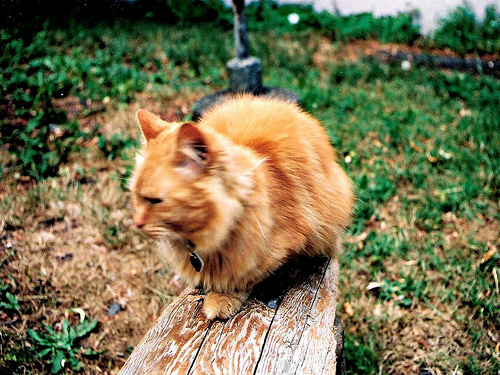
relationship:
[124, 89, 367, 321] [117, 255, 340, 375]
cat on log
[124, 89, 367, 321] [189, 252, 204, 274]
cat with a tag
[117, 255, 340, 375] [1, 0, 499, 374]
log on ground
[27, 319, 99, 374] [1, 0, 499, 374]
weed on ground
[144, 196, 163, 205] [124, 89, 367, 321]
eye of cat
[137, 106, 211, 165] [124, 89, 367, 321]
ears on cat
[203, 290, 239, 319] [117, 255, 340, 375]
foot on log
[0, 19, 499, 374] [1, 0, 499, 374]
grass covering ground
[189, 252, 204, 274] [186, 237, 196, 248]
tag on collar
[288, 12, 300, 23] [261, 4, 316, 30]
bloom on plant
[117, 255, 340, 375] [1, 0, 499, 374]
log laying on ground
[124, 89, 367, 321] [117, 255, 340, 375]
cat sitting on log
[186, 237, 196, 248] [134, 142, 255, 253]
collar on neck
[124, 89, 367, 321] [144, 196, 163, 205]
cat has a eye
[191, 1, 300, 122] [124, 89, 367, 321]
stand behind cat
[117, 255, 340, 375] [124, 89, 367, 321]
log has a cat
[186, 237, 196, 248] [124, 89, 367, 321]
collar on cat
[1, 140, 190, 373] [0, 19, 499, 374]
patch of dead grass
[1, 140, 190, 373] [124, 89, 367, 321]
patch to left of cat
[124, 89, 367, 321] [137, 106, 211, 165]
cat has ears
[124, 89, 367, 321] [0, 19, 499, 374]
cat in grass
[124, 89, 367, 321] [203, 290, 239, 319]
cat has a foot